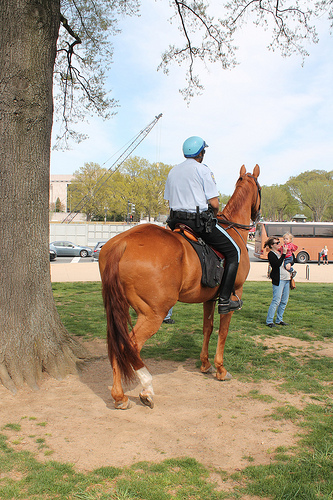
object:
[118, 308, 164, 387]
legs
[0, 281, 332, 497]
green grass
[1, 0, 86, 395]
tree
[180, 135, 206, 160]
helmet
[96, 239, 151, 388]
tail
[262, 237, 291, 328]
woman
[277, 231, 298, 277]
little girl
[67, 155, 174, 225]
tree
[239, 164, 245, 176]
ear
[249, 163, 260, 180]
ear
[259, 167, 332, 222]
tree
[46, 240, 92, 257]
car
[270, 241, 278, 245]
sunglasses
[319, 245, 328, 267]
person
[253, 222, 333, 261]
bus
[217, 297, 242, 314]
foot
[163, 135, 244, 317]
police officer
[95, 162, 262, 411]
horse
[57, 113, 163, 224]
crane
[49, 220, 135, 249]
wall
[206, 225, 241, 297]
leg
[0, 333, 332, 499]
dirt area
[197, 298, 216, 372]
legs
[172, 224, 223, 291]
saddle